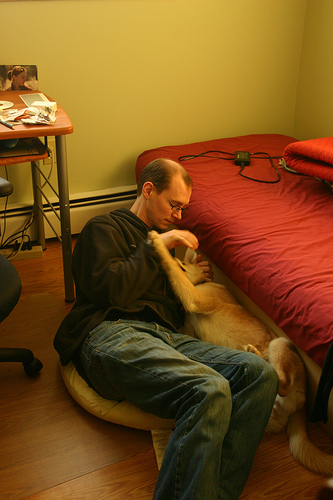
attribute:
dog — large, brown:
[149, 229, 331, 475]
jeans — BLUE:
[85, 316, 279, 498]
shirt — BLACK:
[52, 206, 180, 369]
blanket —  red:
[279, 131, 332, 190]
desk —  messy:
[1, 83, 77, 304]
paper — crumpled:
[21, 95, 76, 140]